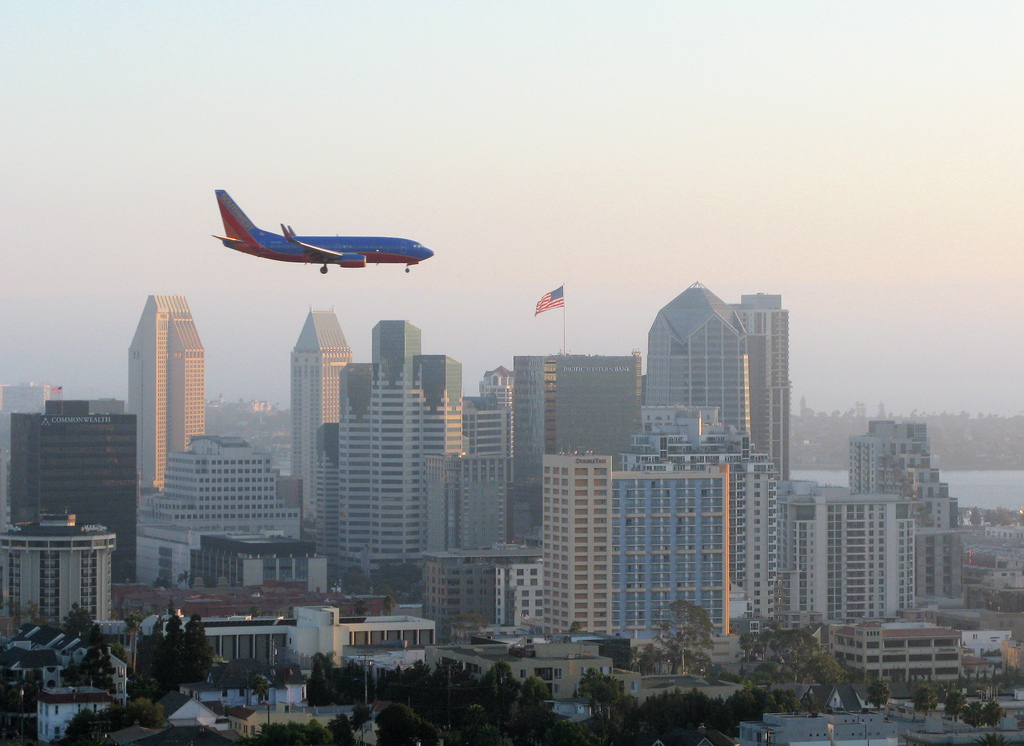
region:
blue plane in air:
[180, 182, 463, 278]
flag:
[517, 261, 579, 323]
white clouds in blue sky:
[9, 43, 70, 111]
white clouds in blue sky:
[838, 126, 912, 218]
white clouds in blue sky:
[898, 296, 966, 344]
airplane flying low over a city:
[14, 29, 1007, 735]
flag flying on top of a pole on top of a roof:
[515, 278, 643, 383]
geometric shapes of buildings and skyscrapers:
[11, 282, 970, 609]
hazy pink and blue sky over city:
[10, 16, 1016, 428]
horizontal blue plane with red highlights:
[206, 184, 438, 276]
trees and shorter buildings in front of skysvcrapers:
[6, 433, 1012, 734]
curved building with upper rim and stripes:
[4, 506, 119, 636]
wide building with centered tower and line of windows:
[126, 601, 440, 688]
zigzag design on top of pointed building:
[643, 276, 748, 365]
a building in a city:
[105, 286, 203, 509]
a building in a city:
[4, 515, 116, 637]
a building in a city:
[10, 396, 143, 597]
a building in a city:
[131, 427, 296, 552]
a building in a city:
[282, 294, 349, 501]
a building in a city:
[344, 316, 453, 552]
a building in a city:
[418, 521, 539, 639]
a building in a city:
[537, 433, 618, 629]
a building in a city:
[611, 456, 742, 641]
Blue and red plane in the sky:
[207, 183, 438, 281]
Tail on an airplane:
[209, 180, 261, 238]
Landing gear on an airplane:
[310, 249, 334, 278]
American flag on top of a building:
[529, 284, 578, 358]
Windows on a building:
[566, 458, 612, 523]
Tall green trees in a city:
[141, 590, 221, 701]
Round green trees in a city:
[909, 685, 1007, 728]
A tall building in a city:
[119, 290, 208, 488]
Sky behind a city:
[2, 0, 1021, 428]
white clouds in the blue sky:
[602, 54, 701, 150]